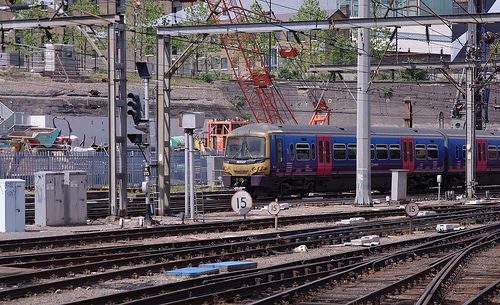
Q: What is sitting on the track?
A: Train.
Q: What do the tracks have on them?
A: Rust.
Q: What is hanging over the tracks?
A: Metal beams.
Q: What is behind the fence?
A: Buildings.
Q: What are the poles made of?
A: Metal.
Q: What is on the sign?
A: 15.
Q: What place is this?
A: Train tracks.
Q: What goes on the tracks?
A: Train.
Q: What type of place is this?
A: Industrial.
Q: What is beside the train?
A: Fence.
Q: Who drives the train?
A: Conductor.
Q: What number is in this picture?
A: 15.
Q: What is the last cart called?
A: Caboose.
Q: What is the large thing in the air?
A: Crane.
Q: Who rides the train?
A: Passengers.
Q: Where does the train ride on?
A: Tracks.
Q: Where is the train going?
A: Down track.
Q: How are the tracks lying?
A: Next to each other.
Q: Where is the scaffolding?
A: Above tracks.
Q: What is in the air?
A: A crane.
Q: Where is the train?
A: On the tracks.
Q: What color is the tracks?
A: Gray.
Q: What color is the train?
A: Blue.